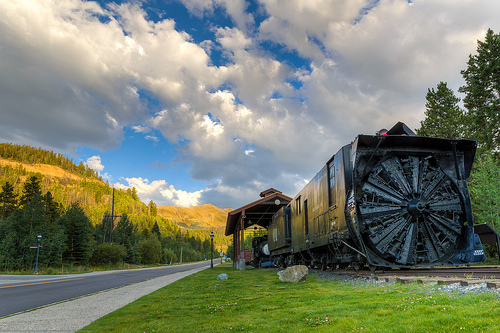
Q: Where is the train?
A: On the tracks.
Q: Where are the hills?
A: Left background.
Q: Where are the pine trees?
A: Along the road.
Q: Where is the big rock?
A: On grass next to train tracks.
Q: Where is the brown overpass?
A: Above the train.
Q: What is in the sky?
A: Clouds.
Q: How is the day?
A: Sunny.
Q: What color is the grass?
A: Green.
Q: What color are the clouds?
A: White.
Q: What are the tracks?
A: Railroad tracks.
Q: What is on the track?
A: A train.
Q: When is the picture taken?
A: Daytime.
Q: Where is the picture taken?
A: At a train station.